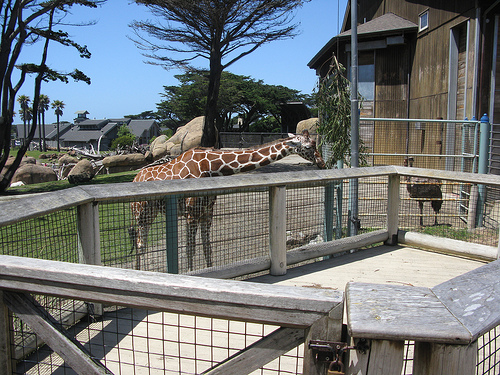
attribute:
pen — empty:
[11, 194, 471, 373]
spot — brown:
[252, 148, 263, 159]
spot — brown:
[169, 159, 184, 177]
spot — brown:
[240, 157, 260, 176]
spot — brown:
[201, 157, 211, 171]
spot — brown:
[159, 170, 169, 179]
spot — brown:
[148, 168, 163, 183]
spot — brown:
[223, 150, 236, 162]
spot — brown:
[154, 171, 172, 186]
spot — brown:
[185, 155, 205, 174]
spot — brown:
[261, 151, 271, 160]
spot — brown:
[260, 145, 279, 161]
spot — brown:
[198, 157, 217, 177]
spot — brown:
[170, 156, 184, 172]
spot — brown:
[265, 150, 280, 165]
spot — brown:
[185, 158, 202, 178]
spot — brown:
[156, 167, 167, 177]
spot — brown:
[219, 165, 232, 176]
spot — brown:
[249, 152, 265, 165]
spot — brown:
[273, 145, 283, 155]